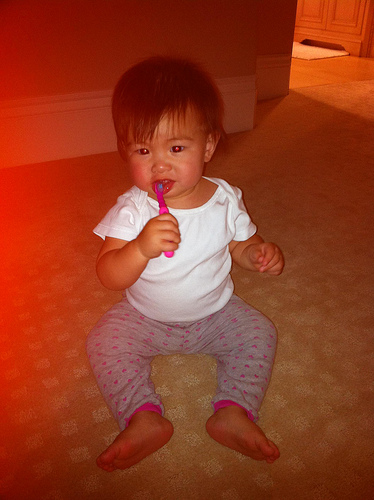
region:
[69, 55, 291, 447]
The girl is a baby.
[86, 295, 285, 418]
She has grey pants on.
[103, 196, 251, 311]
She has a white shirt.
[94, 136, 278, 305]
She is holding a spoon.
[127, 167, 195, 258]
She is putting the spoon in her mouth.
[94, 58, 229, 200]
She has brown hair.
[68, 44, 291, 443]
She is sitting on the floor.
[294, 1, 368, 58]
The cabinet is brown.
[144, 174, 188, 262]
The spoon is pink.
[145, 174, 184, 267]
The spoon is plastic.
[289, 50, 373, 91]
The floor is made of wood.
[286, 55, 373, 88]
The floor is brown.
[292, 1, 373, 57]
The furniture is made of wood.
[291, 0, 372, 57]
The furniture is brown.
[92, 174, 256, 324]
The person is wearing a white top.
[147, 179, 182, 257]
The person is holding a toothbrush.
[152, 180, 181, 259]
The toothbrush is pink.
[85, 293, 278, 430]
The person is wearing gray pants.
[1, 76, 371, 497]
The floor is brown.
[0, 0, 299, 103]
The wall is off white.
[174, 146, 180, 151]
Red in a child's eye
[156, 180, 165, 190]
Bristles on a toothbrush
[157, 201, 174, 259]
Pink handle of a toothbrush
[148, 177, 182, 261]
Child holding a toothbrush in her mouth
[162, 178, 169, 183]
Baby teeth in a child's mouth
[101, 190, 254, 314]
Child wearing a white onesie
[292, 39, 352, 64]
White floor mat on a wooden floor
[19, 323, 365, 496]
White carpeted floor under a child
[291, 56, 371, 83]
Brown wooden flooring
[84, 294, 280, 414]
Hearts on a child's pajama pants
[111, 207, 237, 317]
thes hirt is white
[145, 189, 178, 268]
the toothbrush is orange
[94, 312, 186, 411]
the pants has red dots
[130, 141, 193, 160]
the eyes have red spots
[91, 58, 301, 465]
the baby is seated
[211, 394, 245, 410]
the lining is white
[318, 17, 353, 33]
the door is wooden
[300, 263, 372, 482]
the floor is carpeted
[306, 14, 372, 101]
light is coming from the door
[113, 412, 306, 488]
the legs have no shoes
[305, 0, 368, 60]
two door wooden cabinet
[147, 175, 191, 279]
pink plastic baby spoon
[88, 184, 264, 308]
plain white baby t shirt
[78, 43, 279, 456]
young asian toddler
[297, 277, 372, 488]
white rectangle pattern carpet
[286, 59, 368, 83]
wooden oak planks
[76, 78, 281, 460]
toddler eating a plastic spoon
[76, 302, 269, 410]
heart pattern sweat pants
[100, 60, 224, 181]
thin short black hair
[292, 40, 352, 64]
wooly rug on top of wood floor